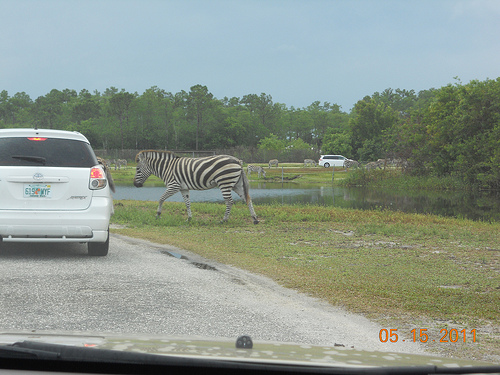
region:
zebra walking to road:
[132, 152, 257, 220]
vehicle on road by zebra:
[1, 127, 116, 259]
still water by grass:
[102, 173, 493, 222]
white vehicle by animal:
[318, 148, 357, 174]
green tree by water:
[351, 78, 499, 181]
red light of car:
[24, 134, 47, 144]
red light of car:
[90, 166, 102, 177]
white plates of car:
[23, 187, 53, 199]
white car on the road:
[3, 110, 119, 262]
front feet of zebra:
[150, 184, 194, 221]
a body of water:
[109, 178, 314, 206]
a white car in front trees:
[311, 147, 362, 172]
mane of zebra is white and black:
[134, 142, 182, 163]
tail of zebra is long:
[236, 160, 262, 225]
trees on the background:
[0, 65, 336, 158]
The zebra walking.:
[134, 150, 264, 233]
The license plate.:
[22, 179, 56, 204]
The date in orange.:
[365, 318, 484, 345]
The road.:
[19, 268, 236, 325]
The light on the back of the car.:
[87, 164, 109, 200]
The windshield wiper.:
[11, 150, 55, 166]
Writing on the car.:
[67, 193, 91, 204]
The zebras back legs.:
[221, 189, 261, 224]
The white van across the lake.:
[319, 152, 353, 177]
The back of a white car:
[2, 127, 114, 258]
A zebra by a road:
[133, 147, 260, 227]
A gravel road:
[1, 229, 436, 371]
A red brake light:
[89, 166, 105, 181]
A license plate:
[24, 181, 51, 199]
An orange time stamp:
[377, 327, 480, 346]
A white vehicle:
[319, 154, 354, 168]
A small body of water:
[108, 181, 498, 227]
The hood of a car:
[1, 331, 496, 373]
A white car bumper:
[0, 221, 110, 243]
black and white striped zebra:
[127, 141, 270, 236]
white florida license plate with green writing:
[10, 178, 60, 202]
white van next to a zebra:
[0, 111, 121, 266]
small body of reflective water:
[109, 176, 499, 238]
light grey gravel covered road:
[2, 222, 441, 374]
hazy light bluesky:
[0, 2, 497, 121]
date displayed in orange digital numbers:
[374, 315, 481, 357]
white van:
[313, 150, 362, 172]